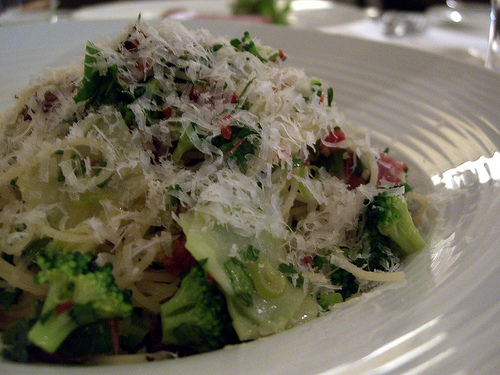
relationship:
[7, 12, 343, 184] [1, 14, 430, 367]
shreddings are on top of food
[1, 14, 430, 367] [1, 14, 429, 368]
food on food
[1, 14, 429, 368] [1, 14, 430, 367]
food full of food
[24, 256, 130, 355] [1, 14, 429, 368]
broccoli on food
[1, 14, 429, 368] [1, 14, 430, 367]
food under food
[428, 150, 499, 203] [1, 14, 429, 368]
light reflecting off food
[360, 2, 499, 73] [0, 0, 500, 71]
glasses on table